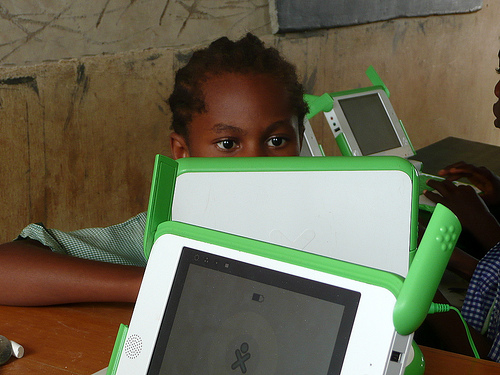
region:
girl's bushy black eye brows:
[190, 110, 258, 129]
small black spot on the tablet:
[239, 280, 279, 312]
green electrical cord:
[428, 290, 459, 325]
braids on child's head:
[165, 14, 303, 91]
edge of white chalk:
[3, 329, 33, 361]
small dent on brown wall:
[13, 60, 64, 118]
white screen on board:
[237, 174, 366, 221]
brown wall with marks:
[43, 86, 143, 158]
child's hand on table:
[416, 154, 487, 209]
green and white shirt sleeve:
[18, 197, 138, 264]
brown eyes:
[209, 123, 302, 155]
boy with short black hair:
[166, 35, 327, 167]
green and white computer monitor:
[311, 77, 413, 168]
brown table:
[23, 304, 104, 374]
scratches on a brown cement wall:
[22, 5, 153, 165]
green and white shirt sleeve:
[49, 219, 146, 257]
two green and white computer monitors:
[133, 149, 370, 373]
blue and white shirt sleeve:
[471, 243, 498, 319]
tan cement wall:
[17, 61, 133, 230]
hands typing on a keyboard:
[407, 152, 499, 224]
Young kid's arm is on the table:
[0, 230, 497, 373]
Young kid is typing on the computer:
[320, 51, 496, 287]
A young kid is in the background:
[420, 35, 495, 260]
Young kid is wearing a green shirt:
[15, 175, 145, 280]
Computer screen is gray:
[155, 256, 346, 371]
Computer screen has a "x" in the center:
[206, 331, 268, 371]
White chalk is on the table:
[0, 335, 40, 365]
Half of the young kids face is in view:
[152, 31, 312, 161]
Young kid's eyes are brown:
[196, 115, 293, 155]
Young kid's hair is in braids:
[164, 26, 316, 135]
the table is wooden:
[27, 269, 132, 373]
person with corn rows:
[156, 28, 311, 161]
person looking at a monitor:
[133, 34, 444, 266]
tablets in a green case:
[110, 150, 478, 362]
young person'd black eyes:
[203, 124, 302, 154]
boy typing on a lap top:
[320, 49, 490, 227]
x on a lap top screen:
[214, 329, 282, 374]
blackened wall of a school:
[14, 16, 139, 186]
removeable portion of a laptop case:
[391, 201, 462, 342]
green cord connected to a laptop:
[434, 297, 491, 372]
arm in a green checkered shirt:
[9, 208, 125, 319]